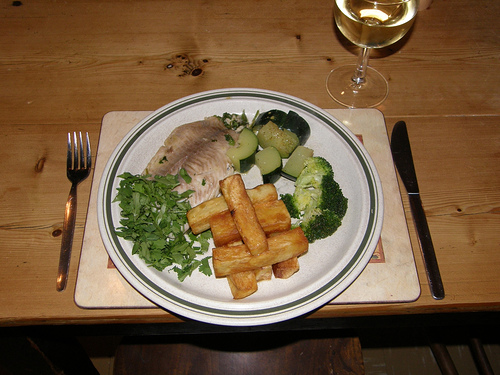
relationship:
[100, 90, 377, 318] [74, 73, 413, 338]
rim of plate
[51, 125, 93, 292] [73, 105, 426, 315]
fork on table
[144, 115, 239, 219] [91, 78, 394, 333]
fish on plate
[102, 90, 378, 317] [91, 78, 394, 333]
stripe on plate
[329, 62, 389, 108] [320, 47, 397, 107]
bottom of glass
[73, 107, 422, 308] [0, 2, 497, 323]
placemat on table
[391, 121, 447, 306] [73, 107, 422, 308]
knife next to placemat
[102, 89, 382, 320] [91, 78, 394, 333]
ring on plate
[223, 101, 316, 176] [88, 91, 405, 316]
zucchini on plate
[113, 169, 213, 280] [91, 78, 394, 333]
parsley on plate